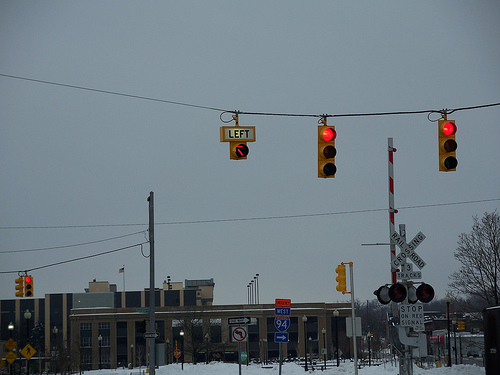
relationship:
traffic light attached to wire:
[434, 119, 460, 173] [1, 72, 500, 117]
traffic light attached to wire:
[315, 124, 338, 181] [1, 72, 500, 117]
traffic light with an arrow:
[216, 113, 256, 163] [235, 146, 246, 157]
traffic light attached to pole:
[335, 263, 349, 299] [347, 262, 361, 375]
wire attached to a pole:
[1, 235, 153, 280] [148, 191, 157, 374]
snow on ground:
[83, 357, 485, 373] [37, 348, 500, 373]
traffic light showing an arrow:
[216, 113, 256, 163] [235, 146, 246, 157]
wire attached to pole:
[1, 235, 153, 280] [148, 191, 157, 374]